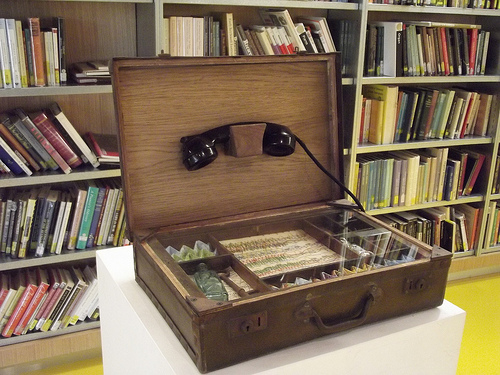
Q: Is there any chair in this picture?
A: No, there are no chairs.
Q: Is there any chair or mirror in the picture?
A: No, there are no chairs or mirrors.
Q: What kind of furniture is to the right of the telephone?
A: The piece of furniture is a shelf.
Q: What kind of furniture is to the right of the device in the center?
A: The piece of furniture is a shelf.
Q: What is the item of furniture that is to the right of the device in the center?
A: The piece of furniture is a shelf.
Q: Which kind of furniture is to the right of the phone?
A: The piece of furniture is a shelf.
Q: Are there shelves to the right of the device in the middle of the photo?
A: Yes, there is a shelf to the right of the phone.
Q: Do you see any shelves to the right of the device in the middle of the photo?
A: Yes, there is a shelf to the right of the phone.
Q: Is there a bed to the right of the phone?
A: No, there is a shelf to the right of the phone.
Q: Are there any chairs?
A: No, there are no chairs.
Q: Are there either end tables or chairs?
A: No, there are no chairs or end tables.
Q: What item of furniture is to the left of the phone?
A: The piece of furniture is a shelf.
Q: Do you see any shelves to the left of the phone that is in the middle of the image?
A: Yes, there is a shelf to the left of the telephone.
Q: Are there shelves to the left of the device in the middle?
A: Yes, there is a shelf to the left of the telephone.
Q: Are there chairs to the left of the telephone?
A: No, there is a shelf to the left of the telephone.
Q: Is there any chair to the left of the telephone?
A: No, there is a shelf to the left of the telephone.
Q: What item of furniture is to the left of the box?
A: The piece of furniture is a shelf.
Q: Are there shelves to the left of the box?
A: Yes, there is a shelf to the left of the box.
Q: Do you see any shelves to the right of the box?
A: No, the shelf is to the left of the box.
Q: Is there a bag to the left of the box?
A: No, there is a shelf to the left of the box.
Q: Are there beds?
A: No, there are no beds.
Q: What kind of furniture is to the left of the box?
A: The piece of furniture is a shelf.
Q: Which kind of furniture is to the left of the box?
A: The piece of furniture is a shelf.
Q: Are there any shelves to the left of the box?
A: Yes, there is a shelf to the left of the box.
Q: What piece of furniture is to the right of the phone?
A: The piece of furniture is a shelf.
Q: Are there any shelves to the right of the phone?
A: Yes, there is a shelf to the right of the phone.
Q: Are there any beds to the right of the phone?
A: No, there is a shelf to the right of the phone.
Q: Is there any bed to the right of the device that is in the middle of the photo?
A: No, there is a shelf to the right of the phone.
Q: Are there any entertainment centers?
A: No, there are no entertainment centers.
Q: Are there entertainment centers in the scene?
A: No, there are no entertainment centers.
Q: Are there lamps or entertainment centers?
A: No, there are no entertainment centers or lamps.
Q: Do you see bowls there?
A: No, there are no bowls.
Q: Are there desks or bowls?
A: No, there are no bowls or desks.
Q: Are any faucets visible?
A: No, there are no faucets.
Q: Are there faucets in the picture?
A: No, there are no faucets.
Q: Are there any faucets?
A: No, there are no faucets.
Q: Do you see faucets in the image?
A: No, there are no faucets.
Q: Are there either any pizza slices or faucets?
A: No, there are no faucets or pizza slices.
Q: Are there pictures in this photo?
A: No, there are no pictures.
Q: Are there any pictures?
A: No, there are no pictures.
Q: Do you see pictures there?
A: No, there are no pictures.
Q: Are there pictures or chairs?
A: No, there are no pictures or chairs.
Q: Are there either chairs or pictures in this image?
A: No, there are no pictures or chairs.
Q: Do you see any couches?
A: No, there are no couches.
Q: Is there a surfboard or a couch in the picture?
A: No, there are no couches or surfboards.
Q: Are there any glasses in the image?
A: No, there are no glasses.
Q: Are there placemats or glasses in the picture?
A: No, there are no glasses or placemats.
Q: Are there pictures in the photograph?
A: No, there are no pictures.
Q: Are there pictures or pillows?
A: No, there are no pictures or pillows.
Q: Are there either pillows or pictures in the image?
A: No, there are no pictures or pillows.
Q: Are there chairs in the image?
A: No, there are no chairs.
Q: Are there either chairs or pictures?
A: No, there are no chairs or pictures.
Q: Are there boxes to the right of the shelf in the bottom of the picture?
A: Yes, there is a box to the right of the shelf.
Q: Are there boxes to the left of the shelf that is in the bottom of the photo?
A: No, the box is to the right of the shelf.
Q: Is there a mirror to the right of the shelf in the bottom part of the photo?
A: No, there is a box to the right of the shelf.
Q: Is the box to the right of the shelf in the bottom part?
A: Yes, the box is to the right of the shelf.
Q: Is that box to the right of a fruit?
A: No, the box is to the right of the shelf.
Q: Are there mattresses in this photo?
A: No, there are no mattresses.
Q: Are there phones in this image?
A: Yes, there is a phone.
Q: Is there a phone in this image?
A: Yes, there is a phone.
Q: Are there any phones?
A: Yes, there is a phone.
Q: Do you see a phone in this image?
A: Yes, there is a phone.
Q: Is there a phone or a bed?
A: Yes, there is a phone.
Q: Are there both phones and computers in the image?
A: No, there is a phone but no computers.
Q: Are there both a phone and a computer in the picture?
A: No, there is a phone but no computers.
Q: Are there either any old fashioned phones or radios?
A: Yes, there is an old fashioned phone.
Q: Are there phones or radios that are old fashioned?
A: Yes, the phone is old fashioned.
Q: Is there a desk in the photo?
A: No, there are no desks.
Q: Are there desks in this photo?
A: No, there are no desks.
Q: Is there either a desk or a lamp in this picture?
A: No, there are no desks or lamps.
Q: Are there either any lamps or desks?
A: No, there are no desks or lamps.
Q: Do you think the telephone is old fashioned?
A: Yes, the telephone is old fashioned.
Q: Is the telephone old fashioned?
A: Yes, the telephone is old fashioned.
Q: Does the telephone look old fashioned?
A: Yes, the telephone is old fashioned.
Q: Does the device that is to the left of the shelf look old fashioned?
A: Yes, the telephone is old fashioned.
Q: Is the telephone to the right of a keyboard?
A: No, the telephone is to the right of a shelf.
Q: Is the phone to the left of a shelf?
A: Yes, the phone is to the left of a shelf.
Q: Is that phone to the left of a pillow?
A: No, the phone is to the left of a shelf.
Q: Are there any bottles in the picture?
A: Yes, there is a bottle.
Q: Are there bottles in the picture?
A: Yes, there is a bottle.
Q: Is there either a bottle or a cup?
A: Yes, there is a bottle.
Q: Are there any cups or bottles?
A: Yes, there is a bottle.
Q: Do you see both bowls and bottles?
A: No, there is a bottle but no bowls.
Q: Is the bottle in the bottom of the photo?
A: Yes, the bottle is in the bottom of the image.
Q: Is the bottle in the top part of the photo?
A: No, the bottle is in the bottom of the image.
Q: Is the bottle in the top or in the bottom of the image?
A: The bottle is in the bottom of the image.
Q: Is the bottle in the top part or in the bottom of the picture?
A: The bottle is in the bottom of the image.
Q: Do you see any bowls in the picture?
A: No, there are no bowls.